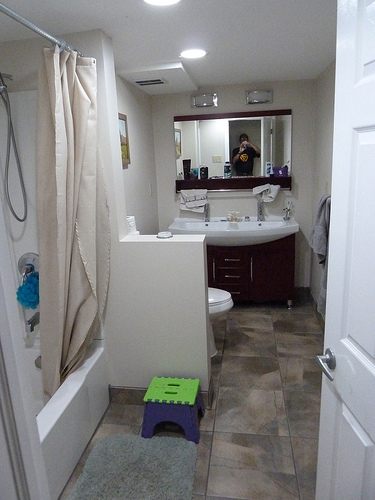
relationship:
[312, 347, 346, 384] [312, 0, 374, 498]
knob on door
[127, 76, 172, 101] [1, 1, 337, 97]
vent on ceiling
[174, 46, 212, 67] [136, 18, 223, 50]
light on ceiling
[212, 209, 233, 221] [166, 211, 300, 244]
toiletries on sink